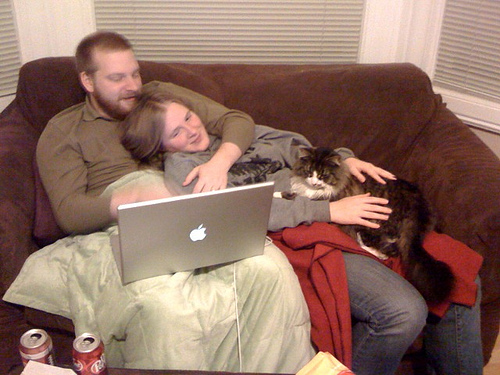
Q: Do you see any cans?
A: Yes, there is a can.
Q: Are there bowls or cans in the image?
A: Yes, there is a can.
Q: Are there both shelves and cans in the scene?
A: No, there is a can but no shelves.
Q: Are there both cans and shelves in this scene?
A: No, there is a can but no shelves.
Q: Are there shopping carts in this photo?
A: No, there are no shopping carts.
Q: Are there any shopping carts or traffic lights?
A: No, there are no shopping carts or traffic lights.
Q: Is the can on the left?
A: Yes, the can is on the left of the image.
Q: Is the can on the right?
A: No, the can is on the left of the image.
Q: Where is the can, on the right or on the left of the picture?
A: The can is on the left of the image.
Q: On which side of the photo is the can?
A: The can is on the left of the image.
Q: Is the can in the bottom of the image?
A: Yes, the can is in the bottom of the image.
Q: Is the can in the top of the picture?
A: No, the can is in the bottom of the image.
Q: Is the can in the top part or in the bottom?
A: The can is in the bottom of the image.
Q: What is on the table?
A: The can is on the table.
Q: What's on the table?
A: The can is on the table.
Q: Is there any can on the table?
A: Yes, there is a can on the table.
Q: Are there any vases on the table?
A: No, there is a can on the table.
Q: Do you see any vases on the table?
A: No, there is a can on the table.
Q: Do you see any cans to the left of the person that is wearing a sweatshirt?
A: Yes, there is a can to the left of the person.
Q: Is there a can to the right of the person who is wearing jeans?
A: No, the can is to the left of the person.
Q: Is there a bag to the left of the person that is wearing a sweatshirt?
A: No, there is a can to the left of the person.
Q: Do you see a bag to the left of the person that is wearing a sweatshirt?
A: No, there is a can to the left of the person.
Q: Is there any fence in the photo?
A: No, there are no fences.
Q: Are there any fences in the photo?
A: No, there are no fences.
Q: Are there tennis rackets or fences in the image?
A: No, there are no fences or tennis rackets.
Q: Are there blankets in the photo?
A: Yes, there is a blanket.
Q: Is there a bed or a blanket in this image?
A: Yes, there is a blanket.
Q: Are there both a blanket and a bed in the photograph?
A: No, there is a blanket but no beds.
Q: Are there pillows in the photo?
A: No, there are no pillows.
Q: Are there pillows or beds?
A: No, there are no pillows or beds.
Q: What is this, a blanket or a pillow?
A: This is a blanket.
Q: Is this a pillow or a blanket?
A: This is a blanket.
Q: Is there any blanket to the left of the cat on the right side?
A: Yes, there is a blanket to the left of the cat.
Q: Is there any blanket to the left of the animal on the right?
A: Yes, there is a blanket to the left of the cat.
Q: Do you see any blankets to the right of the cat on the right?
A: No, the blanket is to the left of the cat.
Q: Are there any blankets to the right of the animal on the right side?
A: No, the blanket is to the left of the cat.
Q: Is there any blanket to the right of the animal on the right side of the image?
A: No, the blanket is to the left of the cat.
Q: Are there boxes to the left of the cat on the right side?
A: No, there is a blanket to the left of the cat.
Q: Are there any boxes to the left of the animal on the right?
A: No, there is a blanket to the left of the cat.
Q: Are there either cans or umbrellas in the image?
A: Yes, there is a can.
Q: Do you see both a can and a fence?
A: No, there is a can but no fences.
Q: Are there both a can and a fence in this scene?
A: No, there is a can but no fences.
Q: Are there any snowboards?
A: No, there are no snowboards.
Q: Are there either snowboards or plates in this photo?
A: No, there are no snowboards or plates.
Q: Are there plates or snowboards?
A: No, there are no snowboards or plates.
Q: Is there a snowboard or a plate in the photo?
A: No, there are no snowboards or plates.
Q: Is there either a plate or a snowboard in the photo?
A: No, there are no snowboards or plates.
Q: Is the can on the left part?
A: Yes, the can is on the left of the image.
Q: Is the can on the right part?
A: No, the can is on the left of the image.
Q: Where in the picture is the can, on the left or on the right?
A: The can is on the left of the image.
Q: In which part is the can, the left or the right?
A: The can is on the left of the image.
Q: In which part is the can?
A: The can is on the left of the image.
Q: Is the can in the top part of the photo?
A: No, the can is in the bottom of the image.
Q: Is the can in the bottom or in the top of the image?
A: The can is in the bottom of the image.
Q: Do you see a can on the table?
A: Yes, there is a can on the table.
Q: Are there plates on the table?
A: No, there is a can on the table.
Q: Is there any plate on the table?
A: No, there is a can on the table.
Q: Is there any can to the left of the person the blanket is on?
A: Yes, there is a can to the left of the person.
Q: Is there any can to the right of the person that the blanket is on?
A: No, the can is to the left of the person.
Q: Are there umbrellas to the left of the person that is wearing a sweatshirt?
A: No, there is a can to the left of the person.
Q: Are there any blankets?
A: Yes, there is a blanket.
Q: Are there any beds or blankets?
A: Yes, there is a blanket.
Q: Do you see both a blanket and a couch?
A: Yes, there are both a blanket and a couch.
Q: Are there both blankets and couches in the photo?
A: Yes, there are both a blanket and a couch.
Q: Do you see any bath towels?
A: No, there are no bath towels.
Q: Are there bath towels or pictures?
A: No, there are no bath towels or pictures.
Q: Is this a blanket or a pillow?
A: This is a blanket.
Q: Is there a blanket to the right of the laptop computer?
A: Yes, there is a blanket to the right of the laptop computer.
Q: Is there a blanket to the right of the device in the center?
A: Yes, there is a blanket to the right of the laptop computer.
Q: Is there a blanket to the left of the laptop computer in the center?
A: No, the blanket is to the right of the laptop.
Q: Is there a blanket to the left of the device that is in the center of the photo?
A: No, the blanket is to the right of the laptop.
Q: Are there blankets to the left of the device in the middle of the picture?
A: No, the blanket is to the right of the laptop.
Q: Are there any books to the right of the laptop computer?
A: No, there is a blanket to the right of the laptop computer.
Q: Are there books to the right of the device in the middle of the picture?
A: No, there is a blanket to the right of the laptop computer.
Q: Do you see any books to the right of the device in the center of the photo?
A: No, there is a blanket to the right of the laptop computer.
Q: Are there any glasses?
A: No, there are no glasses.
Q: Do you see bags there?
A: No, there are no bags.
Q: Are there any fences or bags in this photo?
A: No, there are no bags or fences.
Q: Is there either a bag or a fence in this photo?
A: No, there are no bags or fences.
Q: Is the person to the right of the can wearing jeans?
A: Yes, the person is wearing jeans.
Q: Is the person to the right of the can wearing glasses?
A: No, the person is wearing jeans.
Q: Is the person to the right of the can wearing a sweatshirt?
A: Yes, the person is wearing a sweatshirt.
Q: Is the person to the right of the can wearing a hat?
A: No, the person is wearing a sweatshirt.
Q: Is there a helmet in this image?
A: No, there are no helmets.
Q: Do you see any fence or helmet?
A: No, there are no helmets or fences.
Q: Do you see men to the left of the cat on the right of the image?
A: Yes, there is a man to the left of the cat.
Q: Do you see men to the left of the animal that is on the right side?
A: Yes, there is a man to the left of the cat.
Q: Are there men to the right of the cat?
A: No, the man is to the left of the cat.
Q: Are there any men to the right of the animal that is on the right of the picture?
A: No, the man is to the left of the cat.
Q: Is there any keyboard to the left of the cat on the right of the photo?
A: No, there is a man to the left of the cat.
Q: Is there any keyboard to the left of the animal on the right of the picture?
A: No, there is a man to the left of the cat.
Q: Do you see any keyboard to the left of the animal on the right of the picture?
A: No, there is a man to the left of the cat.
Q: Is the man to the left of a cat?
A: Yes, the man is to the left of a cat.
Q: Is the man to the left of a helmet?
A: No, the man is to the left of a cat.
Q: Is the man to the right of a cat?
A: No, the man is to the left of a cat.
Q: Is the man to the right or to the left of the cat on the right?
A: The man is to the left of the cat.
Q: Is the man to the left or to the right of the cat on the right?
A: The man is to the left of the cat.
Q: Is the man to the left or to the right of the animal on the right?
A: The man is to the left of the cat.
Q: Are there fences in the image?
A: No, there are no fences.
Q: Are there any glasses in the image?
A: No, there are no glasses.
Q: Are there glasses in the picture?
A: No, there are no glasses.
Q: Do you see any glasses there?
A: No, there are no glasses.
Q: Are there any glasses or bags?
A: No, there are no glasses or bags.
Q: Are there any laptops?
A: Yes, there is a laptop.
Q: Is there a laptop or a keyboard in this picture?
A: Yes, there is a laptop.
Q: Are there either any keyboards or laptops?
A: Yes, there is a laptop.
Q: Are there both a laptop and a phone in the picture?
A: No, there is a laptop but no phones.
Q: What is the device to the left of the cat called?
A: The device is a laptop.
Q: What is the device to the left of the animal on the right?
A: The device is a laptop.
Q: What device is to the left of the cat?
A: The device is a laptop.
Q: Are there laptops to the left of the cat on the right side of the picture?
A: Yes, there is a laptop to the left of the cat.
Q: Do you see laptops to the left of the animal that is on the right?
A: Yes, there is a laptop to the left of the cat.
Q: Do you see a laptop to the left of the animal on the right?
A: Yes, there is a laptop to the left of the cat.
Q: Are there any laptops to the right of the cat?
A: No, the laptop is to the left of the cat.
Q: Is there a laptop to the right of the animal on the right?
A: No, the laptop is to the left of the cat.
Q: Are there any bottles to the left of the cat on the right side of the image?
A: No, there is a laptop to the left of the cat.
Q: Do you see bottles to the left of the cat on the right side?
A: No, there is a laptop to the left of the cat.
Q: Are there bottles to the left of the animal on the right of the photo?
A: No, there is a laptop to the left of the cat.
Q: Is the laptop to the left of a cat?
A: Yes, the laptop is to the left of a cat.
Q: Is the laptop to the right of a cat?
A: No, the laptop is to the left of a cat.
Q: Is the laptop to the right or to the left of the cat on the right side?
A: The laptop is to the left of the cat.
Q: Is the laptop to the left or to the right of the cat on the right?
A: The laptop is to the left of the cat.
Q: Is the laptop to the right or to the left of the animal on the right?
A: The laptop is to the left of the cat.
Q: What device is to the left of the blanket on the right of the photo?
A: The device is a laptop.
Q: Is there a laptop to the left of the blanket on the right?
A: Yes, there is a laptop to the left of the blanket.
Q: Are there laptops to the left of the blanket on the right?
A: Yes, there is a laptop to the left of the blanket.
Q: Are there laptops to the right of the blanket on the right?
A: No, the laptop is to the left of the blanket.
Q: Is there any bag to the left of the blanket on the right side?
A: No, there is a laptop to the left of the blanket.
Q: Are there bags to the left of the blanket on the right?
A: No, there is a laptop to the left of the blanket.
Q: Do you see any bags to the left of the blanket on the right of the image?
A: No, there is a laptop to the left of the blanket.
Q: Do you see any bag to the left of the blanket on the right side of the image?
A: No, there is a laptop to the left of the blanket.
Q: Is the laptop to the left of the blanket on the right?
A: Yes, the laptop is to the left of the blanket.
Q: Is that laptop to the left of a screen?
A: No, the laptop is to the left of the blanket.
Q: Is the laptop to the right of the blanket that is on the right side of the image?
A: No, the laptop is to the left of the blanket.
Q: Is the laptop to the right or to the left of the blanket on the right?
A: The laptop is to the left of the blanket.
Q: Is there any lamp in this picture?
A: No, there are no lamps.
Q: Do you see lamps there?
A: No, there are no lamps.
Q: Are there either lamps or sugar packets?
A: No, there are no lamps or sugar packets.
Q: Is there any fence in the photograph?
A: No, there are no fences.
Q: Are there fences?
A: No, there are no fences.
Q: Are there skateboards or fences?
A: No, there are no fences or skateboards.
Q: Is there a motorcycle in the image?
A: No, there are no motorcycles.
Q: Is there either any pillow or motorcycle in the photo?
A: No, there are no motorcycles or pillows.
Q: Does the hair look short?
A: Yes, the hair is short.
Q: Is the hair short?
A: Yes, the hair is short.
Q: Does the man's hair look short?
A: Yes, the hair is short.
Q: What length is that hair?
A: The hair is short.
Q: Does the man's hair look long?
A: No, the hair is short.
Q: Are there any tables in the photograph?
A: Yes, there is a table.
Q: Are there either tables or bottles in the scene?
A: Yes, there is a table.